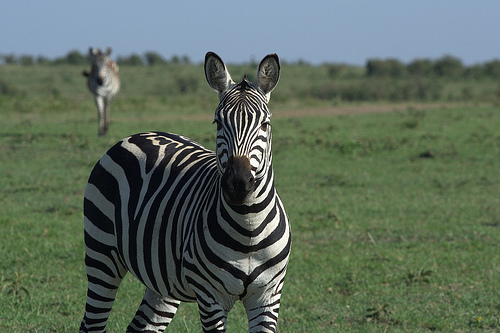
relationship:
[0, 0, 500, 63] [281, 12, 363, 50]
clouds in sky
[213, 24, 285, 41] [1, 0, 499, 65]
clouds in sky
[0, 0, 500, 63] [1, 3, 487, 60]
clouds in sky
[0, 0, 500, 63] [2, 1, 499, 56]
clouds in sky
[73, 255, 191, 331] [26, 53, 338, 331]
back legs on zebra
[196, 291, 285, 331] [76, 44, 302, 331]
legs on front of zebra